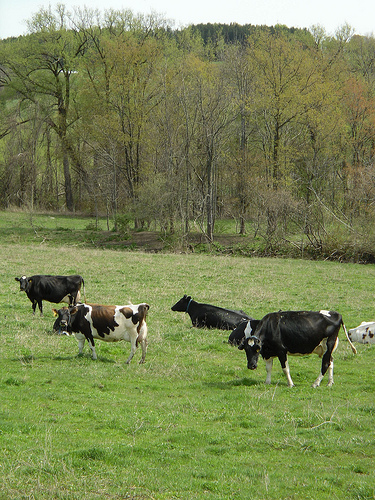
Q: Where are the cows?
A: In a field.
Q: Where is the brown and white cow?
A: Looking at the camera.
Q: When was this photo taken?
A: During the daytime.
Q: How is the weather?
A: Sunny.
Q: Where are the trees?
A: Behind the cows.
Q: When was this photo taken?
A: While the cows were out in a field.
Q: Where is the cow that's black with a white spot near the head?
A: On the far left.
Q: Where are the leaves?
A: On trees.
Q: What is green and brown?
A: Grass.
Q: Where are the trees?
A: Behind cows.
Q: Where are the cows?
A: On the field.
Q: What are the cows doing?
A: Standing and lying down.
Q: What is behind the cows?
A: A forested area.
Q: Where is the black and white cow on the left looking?
A: At the camera.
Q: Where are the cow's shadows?
A: On the grass.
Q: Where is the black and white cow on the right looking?
A: At the ground.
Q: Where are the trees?
A: Next to the field.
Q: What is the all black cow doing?
A: Lying on the grass.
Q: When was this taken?
A: Daytime.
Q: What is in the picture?
A: Cows.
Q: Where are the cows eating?
A: Grass.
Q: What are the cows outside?
A: To graze.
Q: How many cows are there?
A: Six.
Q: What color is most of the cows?
A: Black.